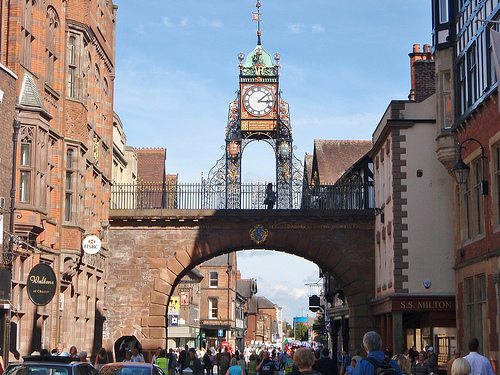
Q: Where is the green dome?
A: On top of the clock.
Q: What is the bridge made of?
A: Brick.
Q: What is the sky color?
A: Blue.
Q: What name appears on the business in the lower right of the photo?
A: S S Milton.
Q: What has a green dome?
A: Clock tower.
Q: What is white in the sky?
A: Clouds.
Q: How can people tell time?
A: Clock on tower.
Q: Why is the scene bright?
A: Sunny day.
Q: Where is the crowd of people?
A: On the street.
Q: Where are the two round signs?
A: Building on left.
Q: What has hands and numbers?
A: Clock.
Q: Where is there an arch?
A: Under clock tower bridge.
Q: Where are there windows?
A: Buildings.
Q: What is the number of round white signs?
A: 1.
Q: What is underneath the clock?
A: A bridge.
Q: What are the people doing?
A: Walk down the street.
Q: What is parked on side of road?
A: Cars.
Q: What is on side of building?
A: Windows.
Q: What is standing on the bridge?
A: A person.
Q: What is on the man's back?
A: A backpack.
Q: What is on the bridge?
A: A fence.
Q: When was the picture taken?
A: During the day.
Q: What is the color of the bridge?
A: Red.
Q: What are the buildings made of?
A: Bricks.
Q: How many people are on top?
A: 1.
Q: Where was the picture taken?
A: Under a clock tower.